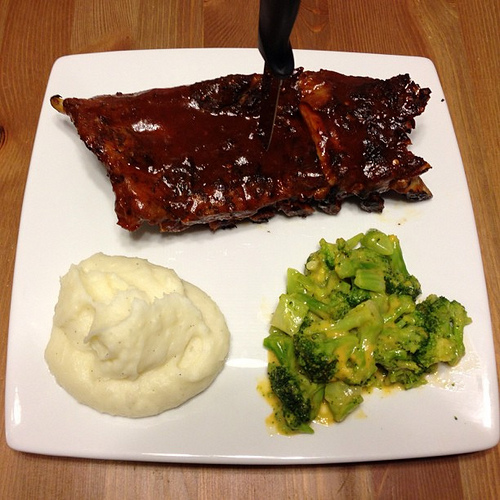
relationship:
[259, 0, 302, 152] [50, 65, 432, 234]
knife stuck in ribs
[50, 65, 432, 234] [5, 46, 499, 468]
ribs on plate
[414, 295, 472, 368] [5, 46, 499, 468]
broccoli on plate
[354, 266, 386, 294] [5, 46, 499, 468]
broccoli on plate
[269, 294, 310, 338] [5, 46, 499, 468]
broccoli on plate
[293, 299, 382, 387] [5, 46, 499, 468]
broccoli on plate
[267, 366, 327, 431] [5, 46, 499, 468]
broccoli on plate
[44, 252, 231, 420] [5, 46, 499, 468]
mashed potatoes on plate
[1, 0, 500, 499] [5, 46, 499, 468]
table under plate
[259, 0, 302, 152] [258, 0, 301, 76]
knife has handle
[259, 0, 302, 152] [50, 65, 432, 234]
knife in ribs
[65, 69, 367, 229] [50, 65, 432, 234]
sauce over ribs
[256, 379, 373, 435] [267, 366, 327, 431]
cheese sauce coats broccoli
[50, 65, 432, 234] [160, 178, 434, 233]
ribs have bones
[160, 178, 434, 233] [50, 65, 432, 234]
bones on side of ribs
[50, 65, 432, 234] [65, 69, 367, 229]
ribs have sauce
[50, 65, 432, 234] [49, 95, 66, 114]
ribs have bone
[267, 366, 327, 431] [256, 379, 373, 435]
broccoli in cheese sauce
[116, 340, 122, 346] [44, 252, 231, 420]
pepper in mashed potatoes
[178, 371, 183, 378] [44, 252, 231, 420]
pepper in mashed potatoes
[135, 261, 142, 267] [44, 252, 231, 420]
pepper in mashed potatoes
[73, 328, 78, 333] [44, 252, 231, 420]
pepper in mashed potatoes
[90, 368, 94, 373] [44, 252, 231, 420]
pepper in mashed potatoes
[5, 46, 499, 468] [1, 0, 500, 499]
plate on table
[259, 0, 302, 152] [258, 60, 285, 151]
knife has blade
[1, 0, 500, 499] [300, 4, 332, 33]
table has knot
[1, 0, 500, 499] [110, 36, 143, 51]
table has knot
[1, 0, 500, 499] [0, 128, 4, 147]
table has knot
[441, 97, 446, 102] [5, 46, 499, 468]
speck on plate